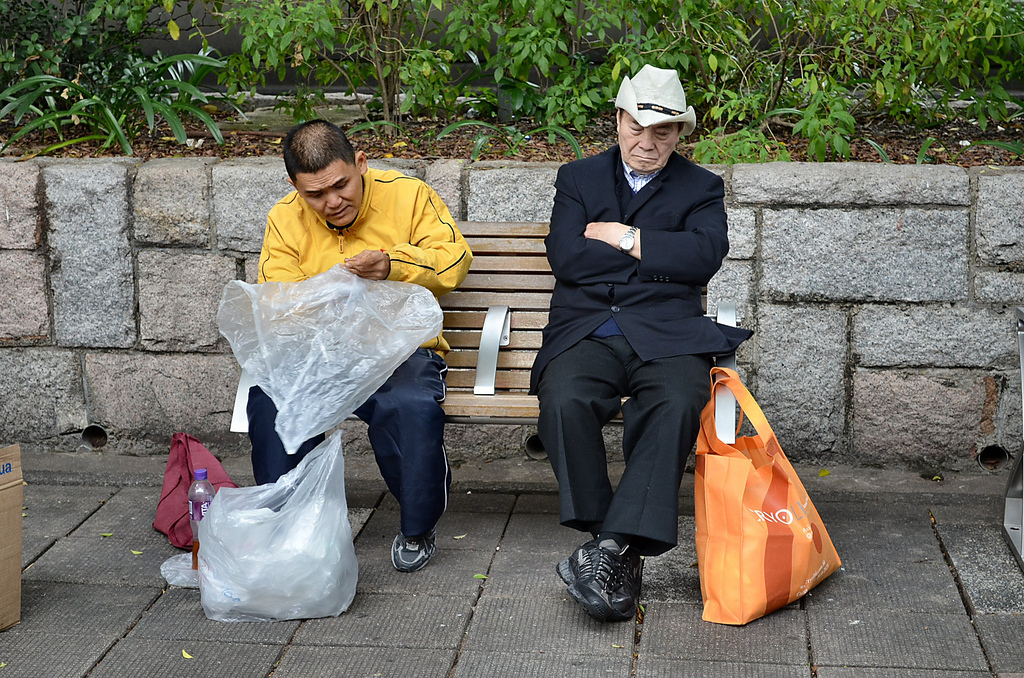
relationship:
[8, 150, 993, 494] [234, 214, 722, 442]
wall next to bench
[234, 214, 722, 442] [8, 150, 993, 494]
bench beside wall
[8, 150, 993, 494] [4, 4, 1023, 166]
wall below hedges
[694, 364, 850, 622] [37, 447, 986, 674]
bag on ground